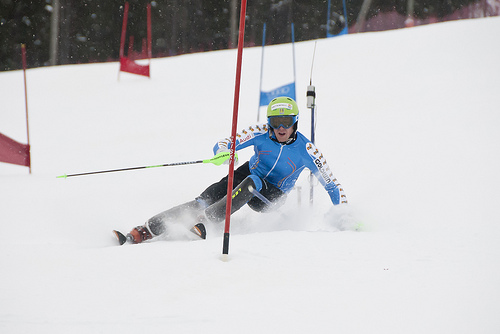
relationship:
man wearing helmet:
[112, 91, 349, 253] [250, 86, 316, 168]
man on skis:
[112, 91, 349, 253] [109, 220, 209, 245]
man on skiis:
[112, 91, 349, 253] [106, 203, 158, 248]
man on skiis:
[112, 91, 349, 253] [181, 208, 223, 248]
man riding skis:
[168, 114, 351, 209] [105, 233, 204, 247]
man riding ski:
[112, 91, 349, 253] [112, 228, 132, 248]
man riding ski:
[112, 91, 349, 253] [193, 220, 205, 242]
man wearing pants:
[112, 91, 349, 253] [151, 162, 283, 227]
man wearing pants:
[168, 114, 351, 209] [149, 165, 279, 243]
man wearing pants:
[168, 114, 351, 209] [134, 162, 297, 238]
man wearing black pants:
[168, 114, 351, 209] [134, 160, 289, 247]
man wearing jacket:
[168, 114, 351, 209] [222, 124, 320, 208]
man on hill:
[168, 114, 351, 209] [5, 19, 498, 328]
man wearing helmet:
[168, 114, 351, 209] [265, 95, 300, 133]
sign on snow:
[120, 58, 152, 78] [363, 75, 440, 172]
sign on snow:
[1, 108, 46, 175] [4, 19, 493, 331]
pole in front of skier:
[209, 21, 259, 256] [109, 85, 366, 261]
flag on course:
[255, 85, 300, 102] [19, 46, 236, 251]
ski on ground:
[190, 226, 212, 234] [2, 19, 495, 333]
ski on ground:
[107, 220, 129, 245] [2, 19, 495, 333]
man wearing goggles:
[168, 114, 351, 209] [268, 111, 303, 132]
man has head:
[112, 91, 349, 253] [265, 96, 298, 140]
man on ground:
[168, 114, 351, 209] [0, 16, 500, 334]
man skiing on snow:
[168, 114, 351, 209] [4, 19, 493, 331]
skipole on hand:
[223, 2, 245, 255] [340, 192, 363, 237]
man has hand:
[112, 91, 349, 253] [340, 192, 363, 237]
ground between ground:
[0, 16, 500, 334] [0, 16, 500, 334]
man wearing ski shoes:
[112, 91, 349, 253] [121, 206, 221, 247]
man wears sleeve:
[112, 91, 349, 253] [305, 136, 352, 228]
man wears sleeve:
[112, 91, 349, 253] [211, 123, 258, 165]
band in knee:
[242, 175, 264, 204] [214, 178, 261, 228]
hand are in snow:
[331, 204, 361, 232] [252, 212, 372, 276]